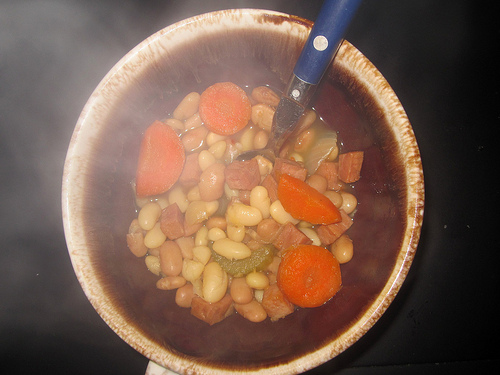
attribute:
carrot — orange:
[138, 121, 186, 200]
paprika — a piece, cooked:
[300, 125, 340, 177]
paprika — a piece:
[208, 242, 282, 278]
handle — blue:
[292, 4, 364, 81]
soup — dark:
[84, 52, 404, 350]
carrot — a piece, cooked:
[203, 81, 248, 140]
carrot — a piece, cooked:
[127, 122, 184, 202]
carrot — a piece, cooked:
[277, 175, 340, 222]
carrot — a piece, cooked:
[275, 242, 340, 312]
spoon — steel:
[228, 24, 350, 185]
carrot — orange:
[248, 179, 365, 258]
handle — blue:
[242, 5, 370, 157]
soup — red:
[128, 112, 371, 339]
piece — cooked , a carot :
[311, 274, 322, 282]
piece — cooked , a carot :
[311, 200, 323, 210]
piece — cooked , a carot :
[227, 101, 239, 108]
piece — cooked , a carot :
[161, 151, 171, 160]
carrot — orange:
[273, 237, 358, 313]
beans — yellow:
[195, 182, 273, 252]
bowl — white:
[56, 10, 430, 372]